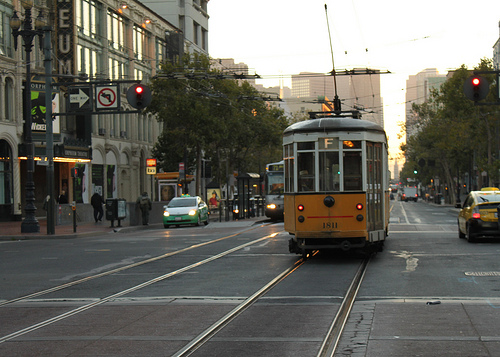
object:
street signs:
[66, 87, 91, 109]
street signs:
[94, 84, 116, 109]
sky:
[206, 0, 500, 150]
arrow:
[102, 91, 116, 106]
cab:
[456, 186, 498, 241]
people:
[132, 191, 152, 227]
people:
[87, 191, 107, 222]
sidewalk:
[2, 221, 161, 239]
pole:
[10, 6, 39, 234]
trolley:
[282, 3, 389, 261]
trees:
[400, 57, 499, 210]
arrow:
[69, 89, 90, 108]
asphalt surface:
[0, 202, 500, 357]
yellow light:
[265, 200, 276, 212]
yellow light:
[187, 208, 197, 217]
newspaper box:
[103, 196, 129, 221]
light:
[354, 204, 365, 210]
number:
[319, 220, 327, 230]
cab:
[161, 193, 210, 229]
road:
[0, 201, 498, 355]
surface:
[0, 201, 500, 355]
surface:
[0, 223, 96, 235]